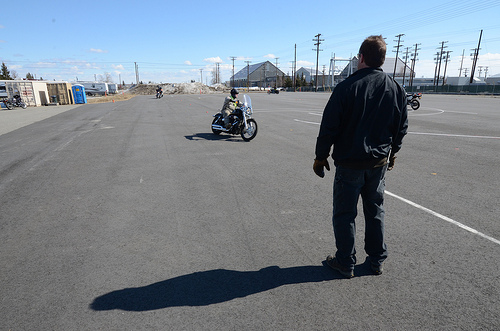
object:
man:
[312, 36, 408, 278]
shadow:
[88, 264, 376, 312]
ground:
[1, 95, 499, 331]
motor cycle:
[211, 94, 258, 142]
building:
[230, 60, 286, 89]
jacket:
[315, 66, 408, 169]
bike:
[156, 89, 163, 99]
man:
[221, 89, 243, 130]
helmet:
[230, 89, 239, 99]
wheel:
[241, 119, 258, 142]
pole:
[315, 34, 319, 92]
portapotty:
[72, 84, 87, 104]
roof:
[72, 84, 84, 88]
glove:
[313, 158, 330, 179]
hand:
[313, 158, 330, 178]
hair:
[359, 34, 386, 67]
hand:
[387, 156, 397, 171]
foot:
[327, 255, 355, 278]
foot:
[365, 256, 384, 275]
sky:
[1, 1, 499, 84]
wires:
[323, 3, 499, 47]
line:
[383, 190, 500, 245]